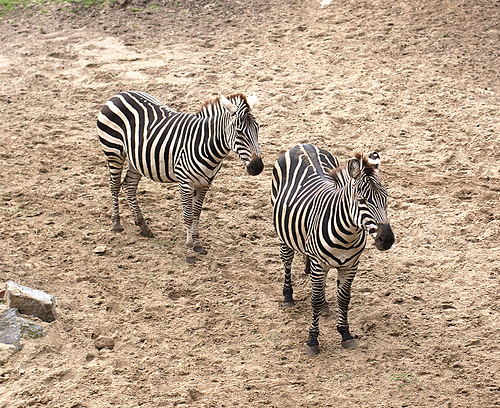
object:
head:
[218, 90, 266, 177]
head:
[346, 148, 394, 251]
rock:
[93, 334, 118, 350]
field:
[0, 4, 500, 406]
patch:
[86, 0, 146, 26]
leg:
[306, 260, 330, 352]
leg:
[334, 262, 358, 323]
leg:
[281, 236, 296, 298]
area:
[335, 325, 353, 339]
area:
[283, 282, 293, 295]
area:
[308, 330, 320, 345]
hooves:
[303, 340, 363, 354]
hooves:
[284, 298, 295, 308]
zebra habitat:
[3, 1, 495, 406]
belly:
[265, 178, 315, 248]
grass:
[382, 365, 422, 387]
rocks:
[1, 282, 58, 367]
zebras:
[95, 88, 395, 353]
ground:
[376, 43, 487, 135]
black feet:
[281, 295, 296, 306]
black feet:
[306, 333, 319, 354]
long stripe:
[300, 145, 331, 183]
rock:
[3, 303, 24, 348]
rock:
[5, 277, 56, 324]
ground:
[2, 2, 85, 405]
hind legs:
[94, 164, 155, 239]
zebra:
[270, 137, 395, 354]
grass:
[312, 33, 417, 133]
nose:
[246, 159, 265, 172]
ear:
[368, 151, 380, 169]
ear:
[346, 157, 360, 176]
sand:
[128, 301, 268, 386]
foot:
[192, 242, 209, 256]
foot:
[184, 252, 195, 264]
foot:
[134, 224, 156, 240]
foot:
[109, 223, 123, 236]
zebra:
[96, 90, 265, 263]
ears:
[347, 150, 389, 178]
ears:
[217, 89, 254, 114]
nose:
[376, 223, 395, 244]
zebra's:
[96, 89, 396, 355]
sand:
[13, 10, 484, 385]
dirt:
[23, 8, 454, 394]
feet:
[307, 325, 321, 354]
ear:
[217, 89, 234, 111]